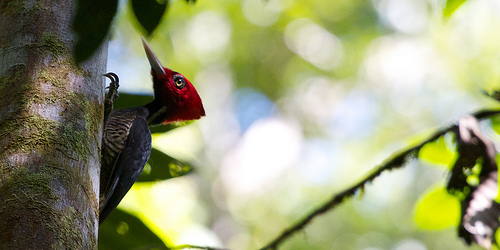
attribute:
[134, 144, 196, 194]
leaf — partially eaten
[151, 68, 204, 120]
head — red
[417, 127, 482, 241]
flowers — yellow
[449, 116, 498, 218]
leaves — white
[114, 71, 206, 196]
woodpecker — feathery, gray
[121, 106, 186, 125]
feathers — bright, red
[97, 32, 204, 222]
woodpecker — yellow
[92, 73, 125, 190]
claws — long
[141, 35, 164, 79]
beak — long, gray